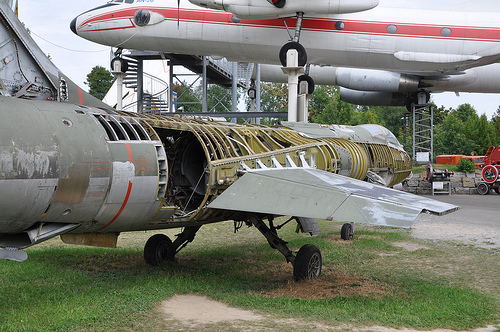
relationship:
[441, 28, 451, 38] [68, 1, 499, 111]
window of airplane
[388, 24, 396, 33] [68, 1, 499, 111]
window of airplane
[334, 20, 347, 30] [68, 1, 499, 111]
window of airplane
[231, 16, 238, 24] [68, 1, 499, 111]
window of airplane